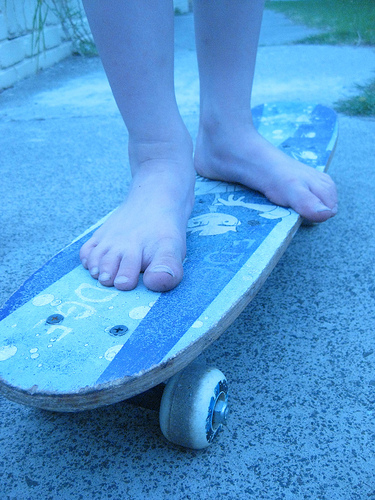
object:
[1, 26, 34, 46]
cement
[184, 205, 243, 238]
logo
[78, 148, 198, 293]
foot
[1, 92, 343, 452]
skateboard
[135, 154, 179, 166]
line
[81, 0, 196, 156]
leg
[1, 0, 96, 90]
wall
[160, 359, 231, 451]
wheels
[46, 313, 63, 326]
screw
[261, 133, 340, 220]
tose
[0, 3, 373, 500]
ground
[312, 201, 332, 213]
toenail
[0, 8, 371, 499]
picture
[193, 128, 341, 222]
bare feet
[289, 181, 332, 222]
toe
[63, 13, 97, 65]
weed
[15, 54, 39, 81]
brick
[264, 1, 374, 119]
grass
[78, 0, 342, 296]
man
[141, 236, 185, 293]
fingure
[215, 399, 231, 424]
nut